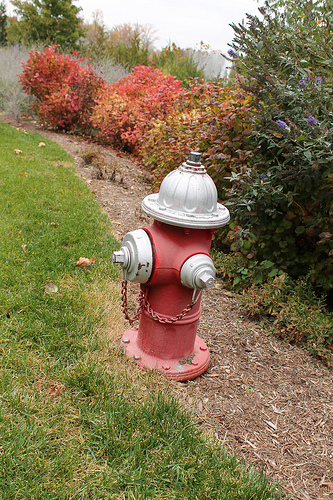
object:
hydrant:
[105, 134, 228, 378]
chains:
[117, 277, 135, 328]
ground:
[26, 235, 313, 497]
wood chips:
[266, 421, 277, 434]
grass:
[7, 177, 22, 195]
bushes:
[25, 51, 40, 78]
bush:
[315, 286, 329, 309]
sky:
[148, 1, 240, 37]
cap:
[140, 147, 229, 226]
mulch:
[91, 154, 123, 181]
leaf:
[75, 251, 90, 267]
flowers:
[304, 114, 316, 131]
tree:
[36, 1, 84, 57]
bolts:
[200, 341, 209, 353]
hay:
[39, 379, 57, 396]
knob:
[111, 232, 154, 278]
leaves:
[51, 95, 61, 109]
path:
[46, 121, 142, 206]